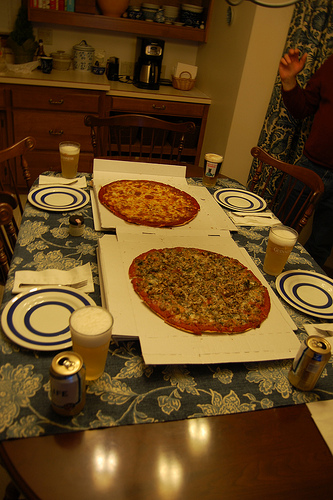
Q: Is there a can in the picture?
A: Yes, there is a can.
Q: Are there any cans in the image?
A: Yes, there is a can.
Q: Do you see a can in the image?
A: Yes, there is a can.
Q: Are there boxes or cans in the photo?
A: Yes, there is a can.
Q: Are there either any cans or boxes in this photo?
A: Yes, there is a can.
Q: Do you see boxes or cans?
A: Yes, there is a can.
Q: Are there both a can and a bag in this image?
A: No, there is a can but no bags.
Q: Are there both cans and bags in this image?
A: No, there is a can but no bags.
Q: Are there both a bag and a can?
A: No, there is a can but no bags.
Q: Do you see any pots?
A: No, there are no pots.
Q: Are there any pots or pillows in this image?
A: No, there are no pots or pillows.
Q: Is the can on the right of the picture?
A: No, the can is on the left of the image.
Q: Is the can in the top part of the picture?
A: No, the can is in the bottom of the image.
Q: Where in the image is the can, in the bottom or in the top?
A: The can is in the bottom of the image.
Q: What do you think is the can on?
A: The can is on the table.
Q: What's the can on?
A: The can is on the table.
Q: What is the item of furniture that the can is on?
A: The piece of furniture is a table.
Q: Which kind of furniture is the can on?
A: The can is on the table.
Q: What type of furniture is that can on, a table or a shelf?
A: The can is on a table.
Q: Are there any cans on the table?
A: Yes, there is a can on the table.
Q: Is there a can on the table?
A: Yes, there is a can on the table.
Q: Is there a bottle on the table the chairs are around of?
A: No, there is a can on the table.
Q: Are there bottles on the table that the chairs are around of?
A: No, there is a can on the table.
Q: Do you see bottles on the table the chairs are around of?
A: No, there is a can on the table.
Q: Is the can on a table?
A: Yes, the can is on a table.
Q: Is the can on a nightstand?
A: No, the can is on a table.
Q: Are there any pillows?
A: No, there are no pillows.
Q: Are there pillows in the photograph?
A: No, there are no pillows.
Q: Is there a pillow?
A: No, there are no pillows.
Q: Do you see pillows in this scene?
A: No, there are no pillows.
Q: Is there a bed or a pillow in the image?
A: No, there are no pillows or beds.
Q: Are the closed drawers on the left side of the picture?
A: Yes, the drawers are on the left of the image.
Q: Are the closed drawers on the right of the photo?
A: No, the drawers are on the left of the image.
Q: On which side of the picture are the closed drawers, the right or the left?
A: The drawers are on the left of the image.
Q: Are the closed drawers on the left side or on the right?
A: The drawers are on the left of the image.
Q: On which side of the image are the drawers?
A: The drawers are on the left of the image.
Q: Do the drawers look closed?
A: Yes, the drawers are closed.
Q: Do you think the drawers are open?
A: No, the drawers are closed.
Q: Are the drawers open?
A: No, the drawers are closed.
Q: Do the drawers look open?
A: No, the drawers are closed.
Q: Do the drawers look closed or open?
A: The drawers are closed.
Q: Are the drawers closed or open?
A: The drawers are closed.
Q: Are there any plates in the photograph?
A: Yes, there is a plate.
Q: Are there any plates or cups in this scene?
A: Yes, there is a plate.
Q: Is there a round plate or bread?
A: Yes, there is a round plate.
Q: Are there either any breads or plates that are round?
A: Yes, the plate is round.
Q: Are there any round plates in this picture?
A: Yes, there is a round plate.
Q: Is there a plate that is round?
A: Yes, there is a plate that is round.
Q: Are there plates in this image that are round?
A: Yes, there is a plate that is round.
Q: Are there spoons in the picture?
A: No, there are no spoons.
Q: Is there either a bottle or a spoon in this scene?
A: No, there are no spoons or bottles.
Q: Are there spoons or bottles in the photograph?
A: No, there are no spoons or bottles.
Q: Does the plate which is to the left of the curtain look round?
A: Yes, the plate is round.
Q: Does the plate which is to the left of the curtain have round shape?
A: Yes, the plate is round.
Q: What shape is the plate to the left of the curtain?
A: The plate is round.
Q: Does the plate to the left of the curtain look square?
A: No, the plate is round.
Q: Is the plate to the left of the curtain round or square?
A: The plate is round.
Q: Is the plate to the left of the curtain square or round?
A: The plate is round.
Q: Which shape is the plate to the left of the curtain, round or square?
A: The plate is round.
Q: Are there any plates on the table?
A: Yes, there is a plate on the table.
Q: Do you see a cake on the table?
A: No, there is a plate on the table.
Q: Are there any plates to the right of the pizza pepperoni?
A: Yes, there is a plate to the right of the pepperoni.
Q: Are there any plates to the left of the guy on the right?
A: Yes, there is a plate to the left of the guy.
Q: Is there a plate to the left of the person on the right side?
A: Yes, there is a plate to the left of the guy.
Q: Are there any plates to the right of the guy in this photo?
A: No, the plate is to the left of the guy.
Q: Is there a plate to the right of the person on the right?
A: No, the plate is to the left of the guy.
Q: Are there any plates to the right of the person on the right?
A: No, the plate is to the left of the guy.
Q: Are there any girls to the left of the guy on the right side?
A: No, there is a plate to the left of the guy.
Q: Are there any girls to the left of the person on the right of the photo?
A: No, there is a plate to the left of the guy.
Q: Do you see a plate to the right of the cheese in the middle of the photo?
A: Yes, there is a plate to the right of the cheese.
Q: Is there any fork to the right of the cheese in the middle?
A: No, there is a plate to the right of the cheese.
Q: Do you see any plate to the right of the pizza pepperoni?
A: Yes, there is a plate to the right of the pepperoni.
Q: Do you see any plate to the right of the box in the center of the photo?
A: Yes, there is a plate to the right of the box.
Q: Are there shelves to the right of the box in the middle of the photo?
A: No, there is a plate to the right of the box.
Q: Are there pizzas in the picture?
A: Yes, there is a pizza.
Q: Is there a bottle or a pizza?
A: Yes, there is a pizza.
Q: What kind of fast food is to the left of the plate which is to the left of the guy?
A: The food is a pizza.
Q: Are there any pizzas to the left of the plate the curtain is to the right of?
A: Yes, there is a pizza to the left of the plate.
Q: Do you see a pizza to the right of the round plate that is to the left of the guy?
A: No, the pizza is to the left of the plate.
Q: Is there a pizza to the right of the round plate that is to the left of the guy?
A: No, the pizza is to the left of the plate.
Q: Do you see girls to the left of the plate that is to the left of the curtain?
A: No, there is a pizza to the left of the plate.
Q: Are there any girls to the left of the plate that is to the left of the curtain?
A: No, there is a pizza to the left of the plate.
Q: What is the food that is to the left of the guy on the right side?
A: The food is a pizza.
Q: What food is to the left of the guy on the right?
A: The food is a pizza.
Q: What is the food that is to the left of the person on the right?
A: The food is a pizza.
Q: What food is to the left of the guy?
A: The food is a pizza.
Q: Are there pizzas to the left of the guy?
A: Yes, there is a pizza to the left of the guy.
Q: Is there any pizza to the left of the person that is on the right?
A: Yes, there is a pizza to the left of the guy.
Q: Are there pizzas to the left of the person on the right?
A: Yes, there is a pizza to the left of the guy.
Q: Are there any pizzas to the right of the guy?
A: No, the pizza is to the left of the guy.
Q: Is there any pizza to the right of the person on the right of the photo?
A: No, the pizza is to the left of the guy.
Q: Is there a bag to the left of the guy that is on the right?
A: No, there is a pizza to the left of the guy.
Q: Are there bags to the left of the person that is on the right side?
A: No, there is a pizza to the left of the guy.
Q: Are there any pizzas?
A: Yes, there is a pizza.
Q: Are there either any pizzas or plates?
A: Yes, there is a pizza.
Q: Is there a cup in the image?
A: Yes, there is a cup.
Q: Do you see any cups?
A: Yes, there is a cup.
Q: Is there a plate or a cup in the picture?
A: Yes, there is a cup.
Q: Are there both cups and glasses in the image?
A: Yes, there are both a cup and glasses.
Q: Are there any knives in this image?
A: No, there are no knives.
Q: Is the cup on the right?
A: Yes, the cup is on the right of the image.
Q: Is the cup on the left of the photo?
A: No, the cup is on the right of the image.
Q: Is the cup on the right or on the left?
A: The cup is on the right of the image.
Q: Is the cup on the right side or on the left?
A: The cup is on the right of the image.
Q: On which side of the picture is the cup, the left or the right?
A: The cup is on the right of the image.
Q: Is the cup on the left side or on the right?
A: The cup is on the right of the image.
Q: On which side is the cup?
A: The cup is on the right of the image.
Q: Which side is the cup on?
A: The cup is on the right of the image.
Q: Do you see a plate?
A: Yes, there is a plate.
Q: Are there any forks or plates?
A: Yes, there is a plate.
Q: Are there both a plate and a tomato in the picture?
A: No, there is a plate but no tomatoes.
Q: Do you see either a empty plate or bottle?
A: Yes, there is an empty plate.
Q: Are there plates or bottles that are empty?
A: Yes, the plate is empty.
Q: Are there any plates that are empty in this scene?
A: Yes, there is an empty plate.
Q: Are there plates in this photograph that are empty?
A: Yes, there is a plate that is empty.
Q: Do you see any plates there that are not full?
A: Yes, there is a empty plate.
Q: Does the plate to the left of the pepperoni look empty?
A: Yes, the plate is empty.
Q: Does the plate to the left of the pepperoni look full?
A: No, the plate is empty.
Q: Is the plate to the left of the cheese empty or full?
A: The plate is empty.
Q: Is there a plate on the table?
A: Yes, there is a plate on the table.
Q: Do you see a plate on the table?
A: Yes, there is a plate on the table.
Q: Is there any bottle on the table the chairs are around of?
A: No, there is a plate on the table.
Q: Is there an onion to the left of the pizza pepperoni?
A: No, there is a plate to the left of the pepperoni.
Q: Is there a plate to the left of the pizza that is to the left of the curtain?
A: Yes, there is a plate to the left of the pizza.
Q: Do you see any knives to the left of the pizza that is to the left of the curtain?
A: No, there is a plate to the left of the pizza.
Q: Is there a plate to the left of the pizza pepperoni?
A: Yes, there is a plate to the left of the pepperoni.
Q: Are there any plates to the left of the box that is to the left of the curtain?
A: Yes, there is a plate to the left of the box.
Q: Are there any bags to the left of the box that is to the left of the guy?
A: No, there is a plate to the left of the box.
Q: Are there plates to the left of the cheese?
A: Yes, there is a plate to the left of the cheese.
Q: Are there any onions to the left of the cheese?
A: No, there is a plate to the left of the cheese.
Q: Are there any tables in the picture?
A: Yes, there is a table.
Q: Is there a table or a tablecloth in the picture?
A: Yes, there is a table.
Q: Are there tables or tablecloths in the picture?
A: Yes, there is a table.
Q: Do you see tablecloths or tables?
A: Yes, there is a table.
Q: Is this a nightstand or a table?
A: This is a table.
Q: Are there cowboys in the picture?
A: No, there are no cowboys.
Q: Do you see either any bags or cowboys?
A: No, there are no cowboys or bags.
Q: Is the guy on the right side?
A: Yes, the guy is on the right of the image.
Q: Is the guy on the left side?
A: No, the guy is on the right of the image.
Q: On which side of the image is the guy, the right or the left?
A: The guy is on the right of the image.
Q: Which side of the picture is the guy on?
A: The guy is on the right of the image.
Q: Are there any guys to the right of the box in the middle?
A: Yes, there is a guy to the right of the box.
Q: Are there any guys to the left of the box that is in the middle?
A: No, the guy is to the right of the box.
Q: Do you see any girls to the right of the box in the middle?
A: No, there is a guy to the right of the box.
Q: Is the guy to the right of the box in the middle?
A: Yes, the guy is to the right of the box.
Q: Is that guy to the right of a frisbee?
A: No, the guy is to the right of the box.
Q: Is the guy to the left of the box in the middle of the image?
A: No, the guy is to the right of the box.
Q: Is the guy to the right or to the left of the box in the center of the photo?
A: The guy is to the right of the box.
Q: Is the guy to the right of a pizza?
A: Yes, the guy is to the right of a pizza.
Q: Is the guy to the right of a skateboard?
A: No, the guy is to the right of a pizza.